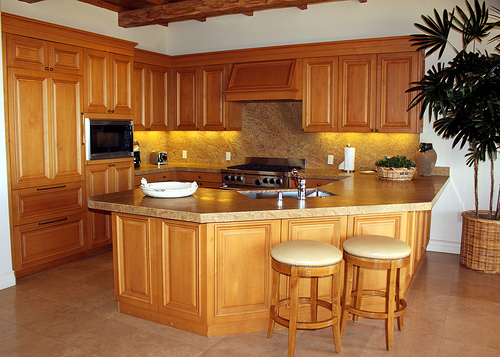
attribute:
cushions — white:
[269, 238, 346, 268]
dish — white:
[135, 169, 206, 207]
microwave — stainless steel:
[83, 115, 133, 157]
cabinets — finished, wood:
[133, 45, 424, 136]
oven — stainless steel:
[225, 171, 290, 186]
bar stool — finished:
[269, 236, 351, 349]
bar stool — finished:
[345, 229, 412, 344]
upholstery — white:
[345, 231, 414, 256]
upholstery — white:
[271, 234, 343, 267]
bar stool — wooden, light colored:
[341, 233, 416, 348]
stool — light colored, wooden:
[264, 227, 349, 354]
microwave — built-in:
[85, 118, 136, 157]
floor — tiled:
[0, 248, 499, 355]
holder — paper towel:
[335, 138, 356, 175]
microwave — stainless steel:
[79, 108, 143, 164]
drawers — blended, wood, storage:
[10, 178, 88, 272]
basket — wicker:
[454, 200, 499, 280]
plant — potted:
[425, 20, 498, 173]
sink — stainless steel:
[230, 180, 334, 202]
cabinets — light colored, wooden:
[313, 78, 392, 130]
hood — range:
[233, 65, 290, 100]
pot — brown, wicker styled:
[456, 203, 498, 275]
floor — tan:
[11, 292, 91, 354]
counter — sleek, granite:
[84, 159, 452, 219]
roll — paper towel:
[342, 143, 357, 172]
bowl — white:
[135, 177, 200, 202]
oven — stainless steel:
[214, 150, 306, 198]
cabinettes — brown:
[211, 217, 403, 301]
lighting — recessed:
[134, 126, 425, 146]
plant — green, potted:
[403, 0, 498, 217]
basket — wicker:
[460, 210, 498, 273]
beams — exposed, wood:
[24, 1, 387, 29]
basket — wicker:
[371, 165, 420, 181]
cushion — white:
[343, 233, 411, 257]